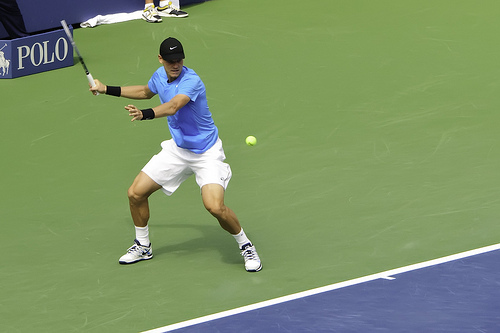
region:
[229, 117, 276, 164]
bright yellow tennis ball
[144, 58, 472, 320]
green and blue tennis court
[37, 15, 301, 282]
man swinging his tennis racket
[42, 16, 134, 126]
white and black tennis racket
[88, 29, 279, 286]
man wearing white shorts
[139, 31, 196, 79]
black hat with nike symbol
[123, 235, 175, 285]
white and black sneakers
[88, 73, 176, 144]
pair of black wristbands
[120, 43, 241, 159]
light blue sports shirt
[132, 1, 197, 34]
black yellow and white sneakers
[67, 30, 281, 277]
player in a Nike hat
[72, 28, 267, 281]
man in a Nike hat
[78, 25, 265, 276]
guy in a Nike hat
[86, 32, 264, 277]
person in a Nike hat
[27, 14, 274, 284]
man addressing the ball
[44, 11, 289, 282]
player addressing the ball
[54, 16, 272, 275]
person addressing the ball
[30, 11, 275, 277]
guy addressing the ball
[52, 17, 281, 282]
man attempting a forehand volley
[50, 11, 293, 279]
man about to hit a forehand shot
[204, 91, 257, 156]
the ball is green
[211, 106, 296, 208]
the ball is green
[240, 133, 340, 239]
the ball is green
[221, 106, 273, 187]
the ball is green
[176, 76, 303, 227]
the ball is green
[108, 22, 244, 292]
Man is playing tennis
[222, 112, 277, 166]
Tennis ball is about to be struck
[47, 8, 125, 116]
Man is holding a tennis racket in his right hand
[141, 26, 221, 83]
Man is wearing a black hat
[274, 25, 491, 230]
Surface behind the tennis court is green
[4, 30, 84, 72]
Polo advertisement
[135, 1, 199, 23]
Man's feet in the background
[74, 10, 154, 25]
Towel laying against the wall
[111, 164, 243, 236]
Man's knees are bent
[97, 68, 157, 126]
Man has sweatbands on his wrists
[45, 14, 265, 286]
man playing a tennis game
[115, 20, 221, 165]
man wearing a blue shirt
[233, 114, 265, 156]
tennis ball in the air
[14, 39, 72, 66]
polo advertisement on tennis court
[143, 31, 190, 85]
man wearing black nike cap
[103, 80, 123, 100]
black colored wrist band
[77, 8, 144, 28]
towel laying on tennis court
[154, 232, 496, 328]
boundary line on tennis court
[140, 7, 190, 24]
white, black, and yellow tennis shoes